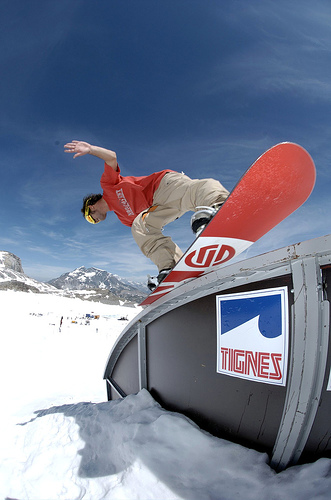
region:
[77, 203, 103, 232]
Yellow goggles on a snowboarder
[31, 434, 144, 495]
Snow on a mountain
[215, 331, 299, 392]
Red and white sign that says Tignes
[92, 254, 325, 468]
Snowboard jumping ramp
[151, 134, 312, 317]
Red and white snowboard being ridden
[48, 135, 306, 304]
Snowboarder jumping on a ski jump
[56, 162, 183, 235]
Orange T-shirt on a snowboarder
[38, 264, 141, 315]
Mountain covered with snow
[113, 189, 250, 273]
Beige pants on a snowboarder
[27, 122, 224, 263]
Blue, clear sky above a snow covered mountain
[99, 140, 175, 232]
the snow skater is wearing a red shirt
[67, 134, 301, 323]
the snow skater is looking down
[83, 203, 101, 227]
the skater is wearing goggles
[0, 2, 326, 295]
the sky is a deep blue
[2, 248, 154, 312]
there are mountain peaks in the background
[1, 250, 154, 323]
the mountains have snow on them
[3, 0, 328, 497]
the photo was taken during the daytime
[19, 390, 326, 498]
the shadow is cast on the snow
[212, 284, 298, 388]
the sign has red lettering on it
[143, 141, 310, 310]
the skateboard is red and white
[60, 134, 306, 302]
a man in a red shirt on a snow board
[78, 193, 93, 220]
yellow safety glasses on a mans face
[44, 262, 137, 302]
a snow covered mountain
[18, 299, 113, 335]
large amount of snow covering the ground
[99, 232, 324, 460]
snow board on a ramp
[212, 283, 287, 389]
logo on a ramp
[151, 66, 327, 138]
blue sky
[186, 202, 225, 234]
Snow shoe on mans foot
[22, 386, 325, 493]
snow on the ground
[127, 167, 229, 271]
Man in khaki pants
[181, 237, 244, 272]
Red and white design under the snowboard.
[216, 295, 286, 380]
Square sign on the platform ramp snowboarder is on.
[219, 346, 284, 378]
Letters on the sign on snowboard ramp platform.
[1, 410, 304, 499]
Snow in front of ramp platform.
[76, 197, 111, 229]
Snow goggles worn by snowboarder.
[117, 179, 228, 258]
Beige pants worn by snowboarder.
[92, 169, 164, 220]
Red t-shirt worn by snowboarder.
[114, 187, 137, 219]
White writing on red t-shirt worn by snowboarder.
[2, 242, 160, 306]
Mountains in the background of photo.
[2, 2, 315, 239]
Blue sky above the snowboarder.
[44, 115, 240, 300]
Snowsurfer is wearing red shirt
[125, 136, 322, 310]
Snowboard is big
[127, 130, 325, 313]
Snowboard is red and white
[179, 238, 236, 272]
snowboard has a white sigh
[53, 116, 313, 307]
Snowboarder is on edge of boat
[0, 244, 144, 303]
Rocky mountains are seen in the background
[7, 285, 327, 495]
Field is covered with snow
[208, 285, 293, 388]
Square sign on boat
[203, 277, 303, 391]
Sign has red letters that says "TIGNES"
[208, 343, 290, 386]
Red letters on sign